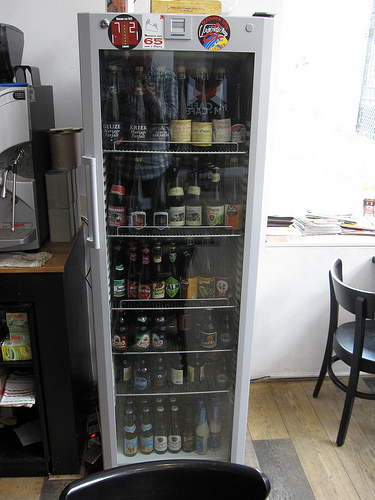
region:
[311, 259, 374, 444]
black wooden chair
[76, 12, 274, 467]
tall refrigerator with glass door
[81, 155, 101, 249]
handle of refrigerator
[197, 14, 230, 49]
round sticker on top of refrigerator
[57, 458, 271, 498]
black plastic wastebasket in front of refrigerator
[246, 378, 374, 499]
wood floor under chair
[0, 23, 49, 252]
espresso machine on cabinet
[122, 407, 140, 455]
beer bottle with a blue label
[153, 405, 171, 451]
beer bottle with a white label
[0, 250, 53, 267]
white towel under espresso machine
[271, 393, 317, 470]
untreated hard wood floors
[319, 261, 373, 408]
black rounded dining chairs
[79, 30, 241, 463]
large gray colored cooler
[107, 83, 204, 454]
rows of different beer bottles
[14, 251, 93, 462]
black and wood table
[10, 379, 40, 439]
red, white, and blue towels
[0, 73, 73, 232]
gray and black coffee machine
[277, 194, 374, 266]
white shelf under window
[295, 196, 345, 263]
piles of multiples sheets paper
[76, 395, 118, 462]
electrical outlet for surge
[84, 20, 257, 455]
a refrigerator containing beer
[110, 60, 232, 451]
a vast selection of beer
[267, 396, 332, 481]
hardwood floor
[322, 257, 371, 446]
a black chair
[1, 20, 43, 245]
an espresso machine on a counter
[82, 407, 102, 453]
a power outlet with its red light on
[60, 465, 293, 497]
top of a black chair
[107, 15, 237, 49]
three stickers on a refrigerator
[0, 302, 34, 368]
a selection of herbal tea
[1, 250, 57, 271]
a dirty napkin on a counter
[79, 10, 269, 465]
a glass door refrigeration unit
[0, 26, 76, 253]
a commercial grade espresso machine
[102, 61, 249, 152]
a shelf of bottled beverages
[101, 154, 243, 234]
a shelf of bottled beverages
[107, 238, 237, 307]
a shelf of bottled beverages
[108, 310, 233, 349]
a shelf of bottled beverages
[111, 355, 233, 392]
a shelf of bottled beverages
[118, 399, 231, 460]
a shelf of bottled beverages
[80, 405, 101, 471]
an electric power strip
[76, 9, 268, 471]
a refrigerated alcoholic beverage display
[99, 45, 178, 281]
reflection of photographer in glass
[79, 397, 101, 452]
power strip on the ground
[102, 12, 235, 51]
colorful stickers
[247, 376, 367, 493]
floor has a wooden appearance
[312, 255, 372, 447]
dark chair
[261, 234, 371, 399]
low wall beside chair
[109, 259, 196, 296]
colorful labels on bottles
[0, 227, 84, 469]
dark shelving unit with brown counter-top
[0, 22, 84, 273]
large machine